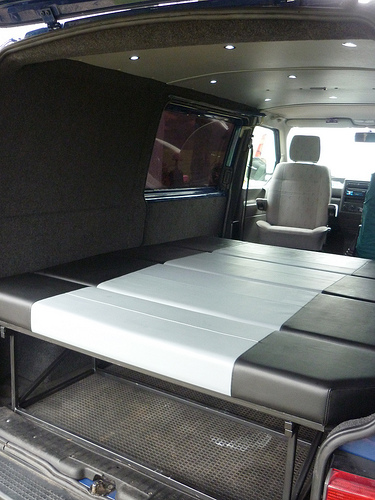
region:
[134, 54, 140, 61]
light on ceiling of car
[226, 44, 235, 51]
light on ceiling of car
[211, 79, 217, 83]
light on ceiling of car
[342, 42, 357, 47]
light on ceiling of car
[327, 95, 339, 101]
light on ceiling of car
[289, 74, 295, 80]
light on ceiling of car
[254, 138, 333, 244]
the driver seat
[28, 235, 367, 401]
the white strip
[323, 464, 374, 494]
the red tail light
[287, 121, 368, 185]
the windshield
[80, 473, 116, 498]
blue on tailgate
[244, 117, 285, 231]
the door on the left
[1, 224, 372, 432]
the back seat folded down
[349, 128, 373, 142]
rear view mirror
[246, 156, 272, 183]
side mirror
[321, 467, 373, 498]
red plastic tail light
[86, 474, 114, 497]
trunk door latch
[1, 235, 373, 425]
black and white cushions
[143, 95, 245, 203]
dark shaded vehicle window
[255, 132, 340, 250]
white cushion vehicle seat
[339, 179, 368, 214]
vehicle radio and CD player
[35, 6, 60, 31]
black metal latch on trunk door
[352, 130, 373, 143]
black vehicle rear mirror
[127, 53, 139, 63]
small lit ceiling light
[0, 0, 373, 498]
open back of a vehicle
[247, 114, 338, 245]
white seat in a vehicle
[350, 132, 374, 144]
review mirror in the vehicle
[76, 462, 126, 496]
latch of the vehicle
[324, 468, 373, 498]
red tail light on the vehicle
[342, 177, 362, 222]
radio in the dash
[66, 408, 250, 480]
storage on the bottom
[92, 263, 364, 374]
seating that is down in the vehicle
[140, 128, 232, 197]
side mirror in the vehicle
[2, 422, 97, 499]
bumper in the vehicle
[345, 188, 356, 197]
light in the vehicle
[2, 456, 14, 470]
Small bumps on a black interior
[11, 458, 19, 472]
Small bumps on a black interior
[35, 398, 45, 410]
Small bumps on a black interior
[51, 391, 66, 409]
Small bumps on a black interior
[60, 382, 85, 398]
Small bumps on a black interior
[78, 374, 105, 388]
Small bumps on a black interior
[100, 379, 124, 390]
Small bumps on a black interior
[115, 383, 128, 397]
Small bumps on a black interior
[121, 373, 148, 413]
Small bumps on a black interior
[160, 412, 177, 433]
Small bumps on a black interior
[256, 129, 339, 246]
the driver seat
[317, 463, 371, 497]
the red tail light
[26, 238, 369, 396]
white strip down middle